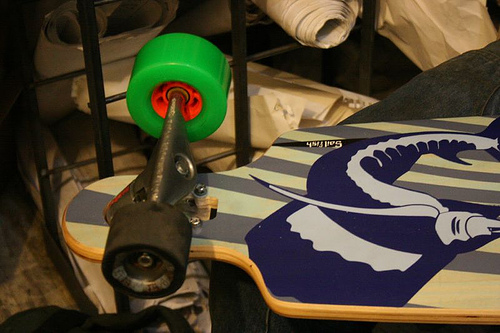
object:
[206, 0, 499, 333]
person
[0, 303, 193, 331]
bag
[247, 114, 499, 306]
picture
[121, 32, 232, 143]
green wheel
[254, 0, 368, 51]
paper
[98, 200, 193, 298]
wheel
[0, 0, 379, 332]
shelf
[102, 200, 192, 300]
skateboard wheel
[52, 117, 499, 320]
board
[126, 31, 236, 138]
wheels